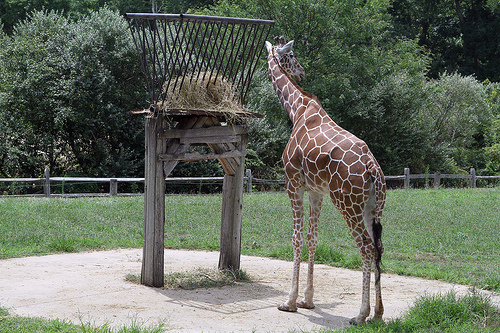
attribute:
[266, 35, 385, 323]
giraffe — spotted, brown, tall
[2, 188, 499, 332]
grass — green, lush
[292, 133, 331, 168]
spots — brown, cream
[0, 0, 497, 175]
trees — leaved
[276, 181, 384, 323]
legs — long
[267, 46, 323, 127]
neck — long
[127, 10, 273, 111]
manger — iron, metal, tall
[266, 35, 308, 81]
head — turned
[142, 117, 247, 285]
stand — wooden, wood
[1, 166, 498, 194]
fence — metal, wooden